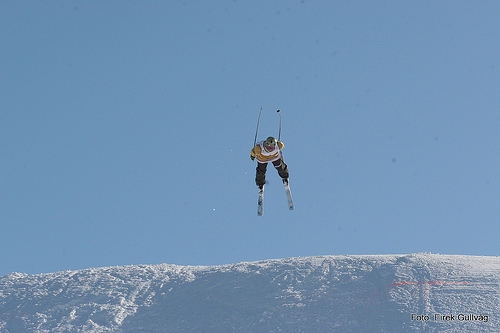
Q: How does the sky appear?
A: Clear and blue.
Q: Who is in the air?
A: A skier.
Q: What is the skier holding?
A: Ski poles.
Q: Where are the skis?
A: Under skiers feet.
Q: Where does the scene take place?
A: At a ski slope.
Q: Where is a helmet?
A: On skier's head.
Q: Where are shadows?
A: On the snow.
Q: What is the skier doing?
A: Performing a trick.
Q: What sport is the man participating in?
A: The man is skiing.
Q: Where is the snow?
A: The snow is on the ground.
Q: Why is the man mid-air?
A: He is skiing.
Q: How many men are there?
A: One.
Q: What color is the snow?
A: White.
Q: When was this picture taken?
A: Daytime.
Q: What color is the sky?
A: Blue.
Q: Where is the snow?
A: Below the man.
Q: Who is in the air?
A: The man.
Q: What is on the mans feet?
A: Skis.